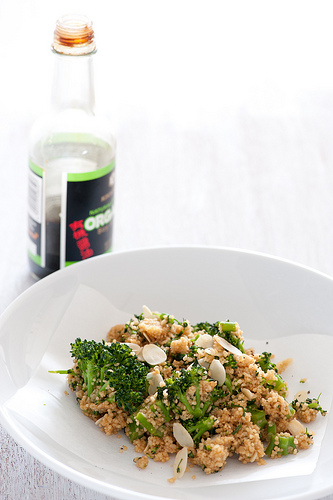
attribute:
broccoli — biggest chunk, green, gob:
[69, 337, 148, 413]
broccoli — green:
[91, 344, 183, 434]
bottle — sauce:
[20, 16, 117, 290]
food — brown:
[43, 300, 330, 488]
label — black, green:
[58, 165, 125, 268]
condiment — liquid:
[41, 226, 68, 249]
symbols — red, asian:
[68, 221, 109, 260]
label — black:
[25, 155, 118, 285]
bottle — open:
[18, 22, 119, 278]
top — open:
[50, 15, 96, 55]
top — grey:
[141, 114, 330, 248]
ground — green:
[283, 86, 305, 114]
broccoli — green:
[63, 334, 146, 407]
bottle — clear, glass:
[32, 6, 139, 293]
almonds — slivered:
[125, 341, 194, 383]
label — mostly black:
[26, 158, 115, 268]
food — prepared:
[109, 338, 228, 451]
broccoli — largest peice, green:
[67, 336, 153, 412]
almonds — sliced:
[141, 344, 166, 364]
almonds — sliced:
[214, 336, 240, 355]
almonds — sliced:
[208, 359, 225, 385]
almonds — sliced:
[170, 422, 193, 447]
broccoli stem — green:
[48, 369, 72, 374]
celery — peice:
[276, 433, 304, 453]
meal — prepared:
[63, 302, 322, 481]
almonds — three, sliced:
[116, 311, 217, 372]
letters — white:
[82, 212, 104, 231]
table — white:
[141, 161, 282, 247]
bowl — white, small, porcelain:
[1, 245, 332, 495]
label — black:
[26, 138, 116, 268]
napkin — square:
[1, 281, 332, 491]